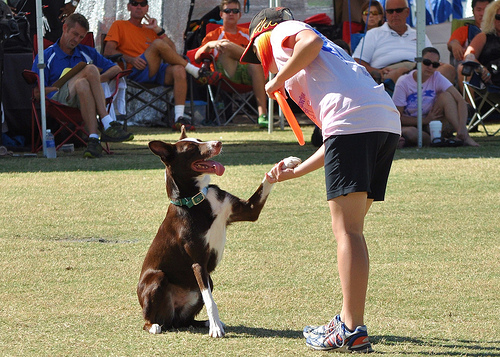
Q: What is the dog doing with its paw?
A: In woman's hand.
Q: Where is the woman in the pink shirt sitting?
A: On ground.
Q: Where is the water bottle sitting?
A: On ground.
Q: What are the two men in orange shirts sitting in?
A: Chairs.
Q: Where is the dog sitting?
A: Grass.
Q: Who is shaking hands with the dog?
A: Woman wearing white shirt.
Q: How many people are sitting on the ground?
A: One.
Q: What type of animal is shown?
A: Dog.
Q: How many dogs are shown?
A: One.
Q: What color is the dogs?
A: Brown and white.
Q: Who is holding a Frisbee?
A: Woman shaking hands with dog.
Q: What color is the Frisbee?
A: Orange.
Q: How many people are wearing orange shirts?
A: Two.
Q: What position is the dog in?
A: Sitting.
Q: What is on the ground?
A: Grass.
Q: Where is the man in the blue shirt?
A: Sitting on a red chair.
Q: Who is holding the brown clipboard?
A: The man sitting in the red chair.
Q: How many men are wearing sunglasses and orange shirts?
A: Two.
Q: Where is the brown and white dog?
A: On the field.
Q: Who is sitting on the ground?
A: A woman in a pink shirt.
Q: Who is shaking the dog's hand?
A: The woman holding the frisbee.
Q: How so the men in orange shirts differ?
A: One is wearing green tennis shoes.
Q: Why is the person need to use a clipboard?
A: He is writing.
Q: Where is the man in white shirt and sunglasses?
A: On the sidelines.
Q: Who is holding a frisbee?
A: The woman in front.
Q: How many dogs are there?
A: One.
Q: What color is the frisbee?
A: Orange.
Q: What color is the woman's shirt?
A: White.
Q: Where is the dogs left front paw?
A: In the woman's hand.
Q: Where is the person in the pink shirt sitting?
A: On the grass.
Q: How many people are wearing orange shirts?
A: Three.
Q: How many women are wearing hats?
A: One.